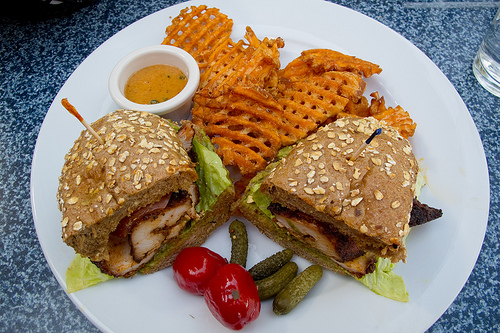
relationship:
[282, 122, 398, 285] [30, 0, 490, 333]
burger on plate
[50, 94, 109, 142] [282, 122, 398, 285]
toothpick on burger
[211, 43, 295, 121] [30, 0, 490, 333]
fries on plate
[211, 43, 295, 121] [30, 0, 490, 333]
fries on top of plate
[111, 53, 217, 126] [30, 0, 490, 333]
sauce on plate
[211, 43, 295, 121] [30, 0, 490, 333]
fries near plate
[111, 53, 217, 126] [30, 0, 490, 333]
sauce near plate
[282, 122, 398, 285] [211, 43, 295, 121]
burger near fries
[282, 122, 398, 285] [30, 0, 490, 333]
burger on top of plate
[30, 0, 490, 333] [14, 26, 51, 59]
plate on table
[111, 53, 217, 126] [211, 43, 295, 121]
sauce near fries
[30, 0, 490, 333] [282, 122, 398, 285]
plate holding burger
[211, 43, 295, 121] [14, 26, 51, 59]
fries near table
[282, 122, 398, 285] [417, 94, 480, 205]
burger on plate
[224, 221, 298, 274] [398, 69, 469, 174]
pickles on plate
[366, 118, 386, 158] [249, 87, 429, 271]
toothpick on sandwich